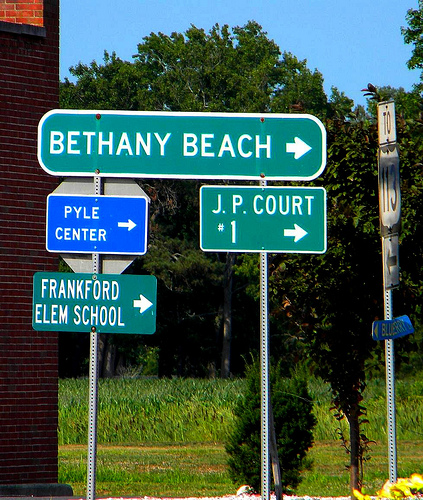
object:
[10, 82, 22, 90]
bricks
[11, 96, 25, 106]
bricks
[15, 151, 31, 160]
bricks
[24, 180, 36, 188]
bricks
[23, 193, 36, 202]
bricks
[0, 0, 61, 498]
building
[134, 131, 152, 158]
letter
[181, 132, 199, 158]
letter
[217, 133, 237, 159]
letter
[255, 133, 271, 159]
letter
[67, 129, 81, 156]
letter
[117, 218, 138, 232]
arrow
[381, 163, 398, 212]
113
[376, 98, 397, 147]
sign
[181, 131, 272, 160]
beach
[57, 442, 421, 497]
grass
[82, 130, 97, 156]
white letter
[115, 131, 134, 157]
white letter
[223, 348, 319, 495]
green bush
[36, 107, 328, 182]
sign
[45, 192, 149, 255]
sign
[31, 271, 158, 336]
sign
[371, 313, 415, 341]
sign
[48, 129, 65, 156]
letter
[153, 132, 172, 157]
letter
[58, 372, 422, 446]
crops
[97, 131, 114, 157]
letter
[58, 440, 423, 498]
field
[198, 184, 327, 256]
sign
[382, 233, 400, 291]
sign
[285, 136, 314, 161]
arrow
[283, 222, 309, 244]
arrow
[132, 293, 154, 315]
arrow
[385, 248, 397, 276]
arrow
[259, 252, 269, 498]
post